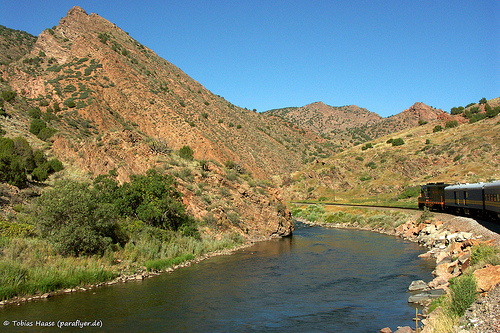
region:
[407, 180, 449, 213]
a black and red train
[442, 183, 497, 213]
blue and orange passenger carts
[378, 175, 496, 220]
a train driving through the mountains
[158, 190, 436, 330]
train tracks along the river bend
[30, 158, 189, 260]
Trees by the river.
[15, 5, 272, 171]
Mountain with shrubs on it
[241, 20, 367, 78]
the clear blue sky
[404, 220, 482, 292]
rocks along the river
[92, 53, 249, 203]
the mountainside has trees on it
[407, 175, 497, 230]
the train is traveling around the river bend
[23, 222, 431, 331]
a narrow river next to the hill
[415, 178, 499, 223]
a passenger train next to the river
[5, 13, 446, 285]
the hills next to the river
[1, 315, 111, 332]
a copyright and name on the bottom of the screen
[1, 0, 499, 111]
the bright blue sky above everything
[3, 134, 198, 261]
green bushes next on the bottom of the hill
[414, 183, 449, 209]
the front of the train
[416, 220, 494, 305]
somewhat colorful stones next to the water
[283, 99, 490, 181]
a few more hills with bushes on them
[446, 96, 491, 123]
a few more bushes on the hill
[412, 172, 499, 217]
train on the tracks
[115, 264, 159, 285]
rocks on the shore line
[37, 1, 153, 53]
mountain peak above water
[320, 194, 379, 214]
tracks going through the country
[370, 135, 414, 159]
green bushes on the hill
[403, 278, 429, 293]
rock in the water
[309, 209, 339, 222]
bushes on the shore line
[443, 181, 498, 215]
cars of the train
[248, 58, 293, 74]
clear blue pretty sky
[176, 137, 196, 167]
bush on the hill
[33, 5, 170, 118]
This is a hill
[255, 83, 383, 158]
This is a hill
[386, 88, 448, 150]
This is a hill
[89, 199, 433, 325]
This is a river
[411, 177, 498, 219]
This is a train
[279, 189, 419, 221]
This is a railway line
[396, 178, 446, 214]
Head of a train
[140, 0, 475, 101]
the blue sky behind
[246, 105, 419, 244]
This is a valley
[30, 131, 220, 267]
This is a shrub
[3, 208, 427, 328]
river in the desert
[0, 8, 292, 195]
tall pointed mountain in the distance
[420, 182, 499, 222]
train on tracks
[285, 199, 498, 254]
train tracks next to a river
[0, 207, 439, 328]
small river in between land areas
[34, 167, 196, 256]
large bush growing by the river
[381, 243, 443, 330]
small boulders on the river bank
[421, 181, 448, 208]
engine of the moving train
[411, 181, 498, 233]
train traveling by a river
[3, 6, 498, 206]
brown desert land